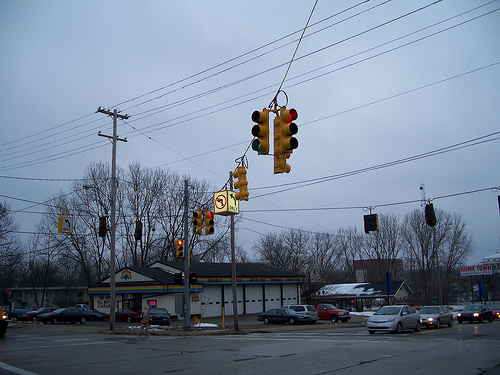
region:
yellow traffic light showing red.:
[274, 96, 296, 191]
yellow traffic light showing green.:
[247, 103, 276, 155]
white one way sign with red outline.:
[210, 183, 243, 225]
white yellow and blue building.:
[97, 254, 299, 324]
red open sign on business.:
[140, 294, 162, 317]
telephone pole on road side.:
[84, 96, 146, 331]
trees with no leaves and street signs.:
[275, 199, 480, 302]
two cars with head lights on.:
[420, 295, 495, 349]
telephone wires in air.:
[10, 83, 265, 183]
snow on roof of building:
[313, 278, 408, 306]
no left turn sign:
[205, 180, 230, 215]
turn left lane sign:
[45, 215, 90, 242]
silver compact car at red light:
[364, 297, 427, 337]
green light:
[186, 210, 206, 240]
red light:
[275, 100, 301, 157]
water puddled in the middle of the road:
[206, 341, 277, 373]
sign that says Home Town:
[453, 256, 498, 283]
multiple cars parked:
[254, 297, 356, 327]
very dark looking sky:
[27, 55, 354, 195]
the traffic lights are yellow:
[46, 97, 313, 267]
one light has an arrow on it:
[208, 187, 239, 217]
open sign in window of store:
[148, 298, 158, 306]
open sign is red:
[149, 300, 156, 307]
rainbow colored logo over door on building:
[119, 267, 131, 283]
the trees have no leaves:
[0, 157, 483, 312]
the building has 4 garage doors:
[198, 281, 301, 320]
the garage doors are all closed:
[201, 280, 303, 321]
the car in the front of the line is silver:
[365, 303, 423, 338]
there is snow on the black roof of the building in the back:
[317, 281, 382, 299]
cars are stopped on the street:
[286, 266, 494, 348]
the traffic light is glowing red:
[155, 216, 217, 278]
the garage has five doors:
[77, 221, 319, 333]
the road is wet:
[30, 309, 474, 371]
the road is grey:
[10, 310, 487, 374]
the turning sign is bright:
[205, 184, 262, 234]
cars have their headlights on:
[407, 288, 498, 332]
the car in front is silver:
[357, 292, 430, 350]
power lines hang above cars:
[4, 1, 497, 260]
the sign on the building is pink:
[86, 266, 183, 319]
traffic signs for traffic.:
[214, 190, 240, 220]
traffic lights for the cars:
[273, 113, 298, 173]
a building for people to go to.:
[86, 258, 313, 320]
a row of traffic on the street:
[363, 296, 497, 338]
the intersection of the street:
[9, 327, 497, 370]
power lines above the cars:
[8, 16, 498, 230]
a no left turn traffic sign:
[51, 215, 76, 236]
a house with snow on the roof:
[315, 282, 408, 310]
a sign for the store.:
[454, 260, 493, 310]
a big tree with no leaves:
[43, 168, 210, 283]